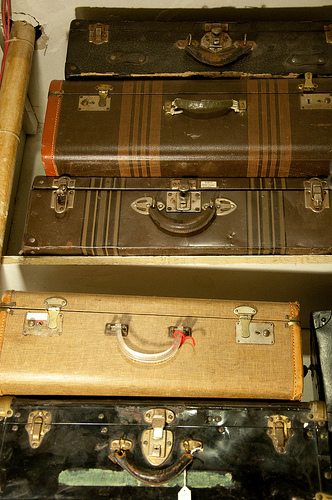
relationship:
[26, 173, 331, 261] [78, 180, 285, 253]
suitcase has stripes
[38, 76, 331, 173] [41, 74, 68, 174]
suitcase has side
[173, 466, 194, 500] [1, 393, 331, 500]
tag on suitcase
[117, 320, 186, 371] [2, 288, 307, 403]
handle on suitcase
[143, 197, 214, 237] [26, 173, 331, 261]
handle on suitcase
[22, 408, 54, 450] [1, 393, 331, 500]
clasp on suitcase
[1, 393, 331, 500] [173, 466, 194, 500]
suitcase with tag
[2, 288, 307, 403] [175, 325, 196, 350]
suitcase with ribbon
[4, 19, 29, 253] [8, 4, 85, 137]
pipe coming out of wall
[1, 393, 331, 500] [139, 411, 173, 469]
suitcase with latch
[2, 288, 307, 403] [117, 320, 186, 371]
suitcase with handle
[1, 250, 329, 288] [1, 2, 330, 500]
wall dividing suitcases